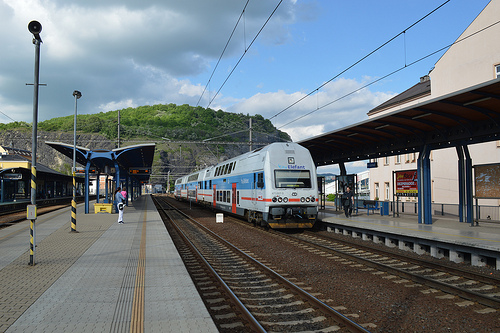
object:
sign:
[389, 169, 426, 197]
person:
[119, 185, 128, 205]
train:
[172, 141, 317, 227]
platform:
[0, 203, 210, 330]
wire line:
[196, 9, 276, 99]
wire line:
[247, 32, 455, 151]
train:
[170, 166, 330, 220]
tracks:
[302, 222, 436, 271]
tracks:
[161, 188, 267, 319]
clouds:
[252, 59, 375, 150]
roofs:
[43, 133, 159, 180]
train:
[166, 136, 326, 238]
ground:
[377, 155, 414, 182]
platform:
[131, 192, 178, 325]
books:
[119, 185, 132, 202]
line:
[128, 192, 156, 332]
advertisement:
[396, 169, 418, 197]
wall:
[367, 140, 416, 216]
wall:
[427, 145, 459, 219]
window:
[367, 166, 409, 213]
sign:
[391, 170, 420, 210]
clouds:
[52, 24, 87, 53]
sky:
[306, 11, 360, 82]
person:
[330, 168, 373, 228]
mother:
[112, 185, 132, 226]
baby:
[119, 189, 134, 204]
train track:
[298, 229, 498, 300]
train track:
[158, 196, 365, 331]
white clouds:
[66, 16, 168, 77]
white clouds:
[183, 77, 398, 147]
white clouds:
[94, 82, 240, 117]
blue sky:
[173, 2, 493, 96]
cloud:
[230, 93, 329, 125]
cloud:
[309, 73, 396, 110]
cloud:
[3, 2, 300, 102]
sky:
[6, 0, 484, 145]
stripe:
[170, 169, 268, 193]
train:
[169, 139, 321, 234]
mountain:
[4, 100, 301, 192]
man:
[330, 169, 361, 232]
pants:
[115, 202, 130, 222]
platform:
[1, 186, 220, 327]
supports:
[80, 148, 127, 196]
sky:
[253, 7, 467, 136]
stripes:
[168, 174, 295, 194]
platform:
[327, 196, 450, 235]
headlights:
[266, 192, 321, 206]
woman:
[113, 184, 133, 225]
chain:
[367, 156, 379, 168]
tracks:
[155, 191, 345, 330]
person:
[113, 184, 127, 230]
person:
[341, 180, 360, 214]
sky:
[5, 3, 467, 135]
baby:
[120, 183, 128, 202]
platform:
[316, 192, 499, 267]